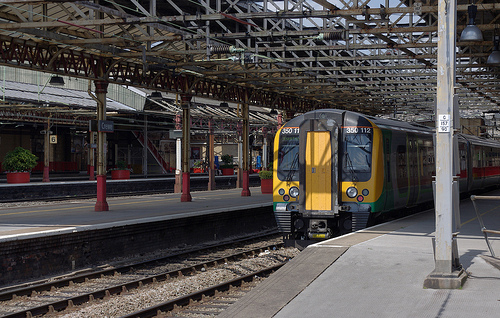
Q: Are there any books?
A: No, there are no books.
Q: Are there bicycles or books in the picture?
A: No, there are no books or bicycles.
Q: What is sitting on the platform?
A: The plant is sitting on the platform.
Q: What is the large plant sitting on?
A: The plant is sitting on the platform.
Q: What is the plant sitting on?
A: The plant is sitting on the platform.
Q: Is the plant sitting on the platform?
A: Yes, the plant is sitting on the platform.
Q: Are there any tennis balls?
A: No, there are no tennis balls.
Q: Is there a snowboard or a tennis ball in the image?
A: No, there are no tennis balls or snowboards.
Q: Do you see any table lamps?
A: No, there are no table lamps.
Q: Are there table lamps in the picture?
A: No, there are no table lamps.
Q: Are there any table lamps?
A: No, there are no table lamps.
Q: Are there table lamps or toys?
A: No, there are no table lamps or toys.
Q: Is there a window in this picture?
A: Yes, there is a window.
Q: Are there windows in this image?
A: Yes, there is a window.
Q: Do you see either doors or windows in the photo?
A: Yes, there is a window.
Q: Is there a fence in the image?
A: No, there are no fences.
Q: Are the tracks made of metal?
A: Yes, the tracks are made of metal.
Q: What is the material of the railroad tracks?
A: The railroad tracks are made of metal.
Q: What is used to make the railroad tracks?
A: The railroad tracks are made of metal.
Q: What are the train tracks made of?
A: The railroad tracks are made of metal.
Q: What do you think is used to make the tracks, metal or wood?
A: The tracks are made of metal.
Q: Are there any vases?
A: No, there are no vases.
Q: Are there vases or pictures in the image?
A: No, there are no vases or pictures.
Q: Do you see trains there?
A: Yes, there is a train.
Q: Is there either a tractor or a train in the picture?
A: Yes, there is a train.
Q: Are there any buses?
A: No, there are no buses.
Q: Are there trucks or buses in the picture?
A: No, there are no buses or trucks.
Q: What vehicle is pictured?
A: The vehicle is a train.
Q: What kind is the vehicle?
A: The vehicle is a train.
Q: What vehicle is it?
A: The vehicle is a train.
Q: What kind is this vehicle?
A: That is a train.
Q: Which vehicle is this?
A: That is a train.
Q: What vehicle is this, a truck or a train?
A: That is a train.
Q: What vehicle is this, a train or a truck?
A: That is a train.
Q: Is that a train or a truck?
A: That is a train.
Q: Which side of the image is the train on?
A: The train is on the right of the image.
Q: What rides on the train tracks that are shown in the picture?
A: The train rides on the train tracks.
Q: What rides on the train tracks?
A: The train rides on the train tracks.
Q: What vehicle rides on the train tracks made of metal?
A: The vehicle is a train.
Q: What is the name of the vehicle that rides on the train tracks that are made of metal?
A: The vehicle is a train.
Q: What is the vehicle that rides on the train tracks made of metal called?
A: The vehicle is a train.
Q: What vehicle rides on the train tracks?
A: The vehicle is a train.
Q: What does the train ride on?
A: The train rides on the train tracks.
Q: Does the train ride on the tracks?
A: Yes, the train rides on the tracks.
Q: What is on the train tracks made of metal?
A: The train is on the train tracks.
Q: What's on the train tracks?
A: The train is on the train tracks.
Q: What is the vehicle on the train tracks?
A: The vehicle is a train.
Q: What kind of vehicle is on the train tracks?
A: The vehicle is a train.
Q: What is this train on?
A: The train is on the tracks.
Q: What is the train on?
A: The train is on the tracks.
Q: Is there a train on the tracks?
A: Yes, there is a train on the tracks.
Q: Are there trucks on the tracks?
A: No, there is a train on the tracks.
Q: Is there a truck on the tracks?
A: No, there is a train on the tracks.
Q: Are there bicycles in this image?
A: No, there are no bicycles.